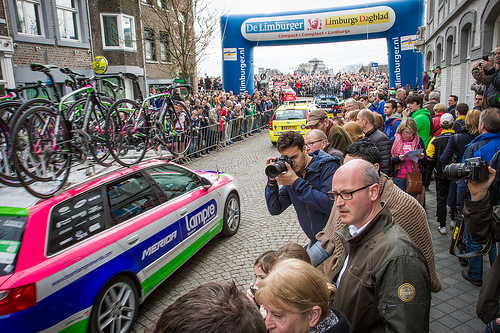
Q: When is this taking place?
A: Daytime.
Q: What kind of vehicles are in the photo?
A: Bicycles and cars.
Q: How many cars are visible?
A: Three.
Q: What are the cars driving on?
A: Street.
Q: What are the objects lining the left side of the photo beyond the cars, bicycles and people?
A: Buildings.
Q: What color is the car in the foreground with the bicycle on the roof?
A: Pink, blue, white and green.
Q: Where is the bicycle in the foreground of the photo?
A: Roof of car.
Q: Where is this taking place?
A: On a street where a large bicycle race is taking place.